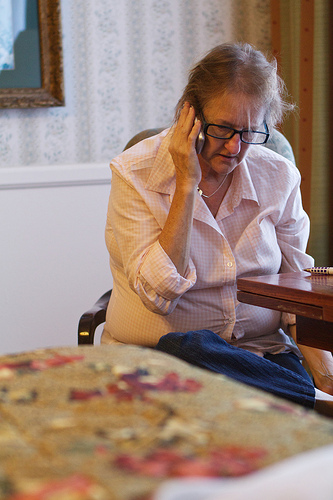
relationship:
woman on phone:
[99, 43, 332, 418] [183, 102, 205, 155]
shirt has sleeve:
[100, 123, 315, 356] [106, 158, 199, 316]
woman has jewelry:
[99, 43, 332, 418] [197, 174, 229, 199]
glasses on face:
[193, 96, 271, 147] [199, 97, 266, 177]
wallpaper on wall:
[2, 1, 274, 167] [2, 2, 273, 357]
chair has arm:
[79, 126, 296, 347] [79, 287, 113, 345]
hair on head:
[170, 41, 299, 144] [188, 46, 268, 175]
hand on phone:
[168, 100, 203, 184] [183, 102, 205, 155]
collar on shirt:
[146, 119, 261, 238] [100, 123, 315, 356]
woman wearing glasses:
[99, 43, 332, 418] [193, 96, 271, 147]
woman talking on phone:
[99, 43, 332, 418] [183, 102, 205, 155]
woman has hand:
[99, 43, 332, 418] [168, 100, 203, 184]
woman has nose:
[99, 43, 332, 418] [224, 132, 242, 156]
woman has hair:
[99, 43, 332, 418] [170, 41, 299, 144]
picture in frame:
[1, 1, 42, 90] [1, 2, 65, 111]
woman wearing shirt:
[99, 43, 332, 418] [100, 123, 315, 356]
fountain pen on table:
[303, 267, 331, 277] [235, 266, 333, 325]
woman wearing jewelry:
[99, 43, 332, 418] [197, 174, 229, 199]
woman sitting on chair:
[99, 43, 332, 418] [79, 126, 296, 347]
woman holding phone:
[99, 43, 332, 418] [183, 102, 205, 155]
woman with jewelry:
[99, 43, 332, 418] [197, 174, 229, 199]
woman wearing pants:
[99, 43, 332, 418] [157, 328, 317, 408]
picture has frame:
[1, 1, 42, 90] [1, 2, 65, 111]